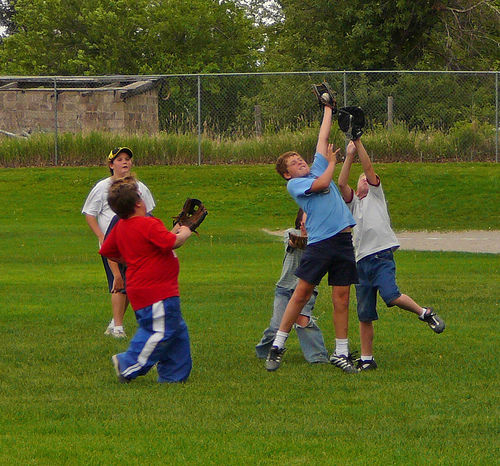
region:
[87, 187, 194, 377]
boy wearing red shirt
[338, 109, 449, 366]
boy wearing white shirt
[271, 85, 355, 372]
boy catching the baseball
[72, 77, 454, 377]
boys running to catch baseball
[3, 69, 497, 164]
fence along the grass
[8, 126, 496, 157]
long grass behind the fence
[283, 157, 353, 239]
blue shirt of boy catching the ball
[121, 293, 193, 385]
blue pants with white stripe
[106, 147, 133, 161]
yellow and black hat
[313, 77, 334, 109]
glove with baseball in it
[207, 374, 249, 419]
short green and brown grass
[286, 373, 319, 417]
short green and brown grass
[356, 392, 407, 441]
short green and brown grass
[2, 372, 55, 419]
short green and brown grass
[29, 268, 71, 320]
short green and brown grass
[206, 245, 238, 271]
short green and brown grass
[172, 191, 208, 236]
child wearing black baseball glove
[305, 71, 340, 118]
child wearing black baseball glove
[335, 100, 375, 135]
child wearing black baseball glove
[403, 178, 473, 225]
short green and brown grass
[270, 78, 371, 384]
boy catching a ball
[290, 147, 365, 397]
boy wearing blue shirt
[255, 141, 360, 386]
boy wearing blue shorts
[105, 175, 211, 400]
boy holding a glove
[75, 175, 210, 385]
boy wearing blue pants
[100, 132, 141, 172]
boy wearing yellow hat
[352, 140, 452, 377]
boy wearing gray shirt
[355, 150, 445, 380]
boy wearing blue shorts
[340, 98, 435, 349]
boy wearing a glove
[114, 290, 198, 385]
Boy is wearing pants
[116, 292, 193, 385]
Boy is wearing blue and white pants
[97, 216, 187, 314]
Boy is wearing a shirt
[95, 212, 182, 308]
Boy is wearing a red shirt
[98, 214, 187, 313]
Boy is wearing a t-shirt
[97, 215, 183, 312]
Boy is wearing a red t-shirt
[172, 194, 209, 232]
Boy is wearing a baseball glove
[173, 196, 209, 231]
Boy is wearing a brown baseball glove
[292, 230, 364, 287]
Boy is wearing shorts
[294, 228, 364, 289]
Boy is wearing blue shorts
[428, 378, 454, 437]
There is green grass that is visible here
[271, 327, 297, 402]
This boy is wearing a black shoe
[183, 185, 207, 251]
This boy is wearing a glove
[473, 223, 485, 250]
There is light brown gravel on the field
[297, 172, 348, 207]
This boy is wearing a blue t-shirt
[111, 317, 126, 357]
This boy is wearing some white shoes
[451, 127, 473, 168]
There is grass that is in the distance here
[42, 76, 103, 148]
There is a dilapidated stone shed here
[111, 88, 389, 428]
Jason Zander will take over ownership of this photo